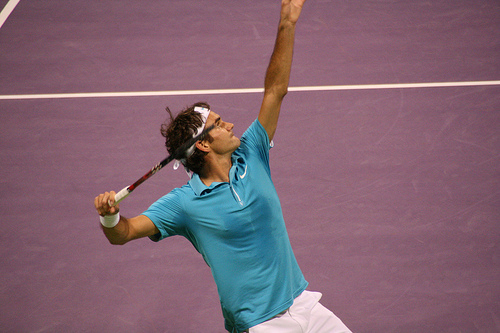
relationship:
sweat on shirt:
[219, 186, 282, 239] [157, 173, 346, 294]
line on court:
[61, 69, 206, 121] [71, 20, 269, 90]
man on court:
[86, 65, 320, 262] [71, 20, 269, 90]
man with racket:
[86, 65, 320, 262] [114, 124, 212, 202]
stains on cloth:
[222, 203, 252, 227] [213, 183, 284, 269]